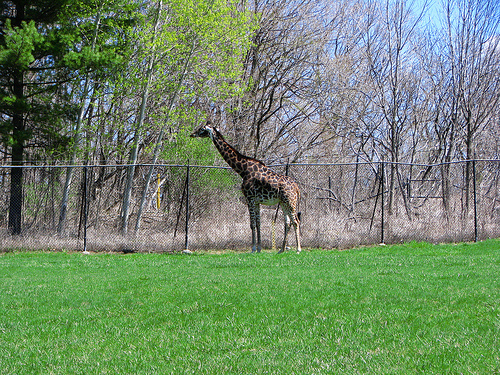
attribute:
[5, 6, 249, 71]
leaves — tree, green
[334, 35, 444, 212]
trees — bare, dead looking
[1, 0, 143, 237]
pine tree — tall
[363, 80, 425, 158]
trees — dead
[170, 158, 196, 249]
poles — metal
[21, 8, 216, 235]
trees — green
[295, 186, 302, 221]
tail — long, brown, white and black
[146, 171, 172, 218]
pipe — yellow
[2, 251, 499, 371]
grass — bright, green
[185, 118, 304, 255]
giraffe — brown, white, tall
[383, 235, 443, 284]
grass — green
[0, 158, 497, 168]
pole — metal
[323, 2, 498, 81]
sky — blue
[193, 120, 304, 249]
giraffe — orange, brown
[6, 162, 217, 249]
fence — chain link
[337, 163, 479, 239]
fence — enclosure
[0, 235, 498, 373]
field — large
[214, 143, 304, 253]
spots — brown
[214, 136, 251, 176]
neck — long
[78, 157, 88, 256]
fencepost — black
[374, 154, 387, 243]
fencepost — black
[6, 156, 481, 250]
fence — barely visible, gray, chain link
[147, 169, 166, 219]
pole — yellow